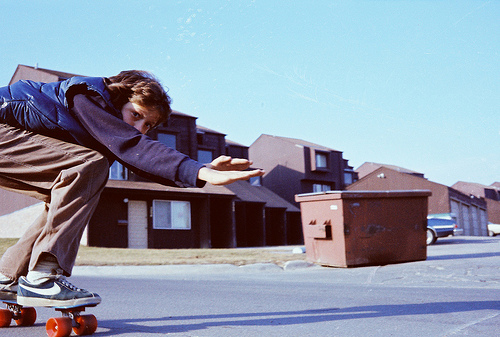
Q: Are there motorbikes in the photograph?
A: No, there are no motorbikes.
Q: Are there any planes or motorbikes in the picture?
A: No, there are no motorbikes or planes.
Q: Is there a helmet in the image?
A: No, there are no helmets.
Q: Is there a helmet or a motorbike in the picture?
A: No, there are no helmets or motorcycles.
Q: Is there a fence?
A: No, there are no fences.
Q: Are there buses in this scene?
A: No, there are no buses.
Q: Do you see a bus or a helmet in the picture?
A: No, there are no buses or helmets.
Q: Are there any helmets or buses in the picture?
A: No, there are no buses or helmets.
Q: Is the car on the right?
A: Yes, the car is on the right of the image.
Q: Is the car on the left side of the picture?
A: No, the car is on the right of the image.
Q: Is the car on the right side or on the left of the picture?
A: The car is on the right of the image.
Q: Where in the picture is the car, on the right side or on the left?
A: The car is on the right of the image.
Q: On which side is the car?
A: The car is on the right of the image.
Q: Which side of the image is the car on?
A: The car is on the right of the image.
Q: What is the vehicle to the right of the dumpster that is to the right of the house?
A: The vehicle is a car.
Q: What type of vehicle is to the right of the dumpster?
A: The vehicle is a car.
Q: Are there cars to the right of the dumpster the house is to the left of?
A: Yes, there is a car to the right of the dumpster.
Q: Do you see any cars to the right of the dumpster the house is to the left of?
A: Yes, there is a car to the right of the dumpster.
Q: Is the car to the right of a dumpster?
A: Yes, the car is to the right of a dumpster.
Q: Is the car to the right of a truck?
A: No, the car is to the right of a dumpster.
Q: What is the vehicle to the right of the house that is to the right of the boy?
A: The vehicle is a car.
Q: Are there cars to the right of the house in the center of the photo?
A: Yes, there is a car to the right of the house.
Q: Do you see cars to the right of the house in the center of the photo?
A: Yes, there is a car to the right of the house.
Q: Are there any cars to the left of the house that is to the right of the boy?
A: No, the car is to the right of the house.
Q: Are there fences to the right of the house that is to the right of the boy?
A: No, there is a car to the right of the house.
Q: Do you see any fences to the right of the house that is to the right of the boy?
A: No, there is a car to the right of the house.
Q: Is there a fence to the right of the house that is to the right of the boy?
A: No, there is a car to the right of the house.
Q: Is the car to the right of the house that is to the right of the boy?
A: Yes, the car is to the right of the house.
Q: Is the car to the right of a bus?
A: No, the car is to the right of the house.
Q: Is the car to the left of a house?
A: No, the car is to the right of a house.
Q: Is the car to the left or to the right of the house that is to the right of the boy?
A: The car is to the right of the house.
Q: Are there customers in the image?
A: No, there are no customers.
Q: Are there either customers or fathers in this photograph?
A: No, there are no customers or fathers.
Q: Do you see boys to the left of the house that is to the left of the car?
A: Yes, there is a boy to the left of the house.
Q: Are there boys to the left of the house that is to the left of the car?
A: Yes, there is a boy to the left of the house.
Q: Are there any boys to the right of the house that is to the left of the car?
A: No, the boy is to the left of the house.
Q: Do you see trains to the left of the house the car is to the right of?
A: No, there is a boy to the left of the house.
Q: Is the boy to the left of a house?
A: Yes, the boy is to the left of a house.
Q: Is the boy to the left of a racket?
A: No, the boy is to the left of a house.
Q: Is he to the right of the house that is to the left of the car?
A: No, the boy is to the left of the house.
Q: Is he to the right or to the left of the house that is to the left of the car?
A: The boy is to the left of the house.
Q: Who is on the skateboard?
A: The boy is on the skateboard.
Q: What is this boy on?
A: The boy is on the skateboard.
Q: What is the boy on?
A: The boy is on the skateboard.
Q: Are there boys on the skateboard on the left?
A: Yes, there is a boy on the skateboard.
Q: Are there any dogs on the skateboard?
A: No, there is a boy on the skateboard.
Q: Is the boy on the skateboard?
A: Yes, the boy is on the skateboard.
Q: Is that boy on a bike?
A: No, the boy is on the skateboard.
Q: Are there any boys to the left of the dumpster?
A: Yes, there is a boy to the left of the dumpster.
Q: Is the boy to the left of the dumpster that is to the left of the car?
A: Yes, the boy is to the left of the dumpster.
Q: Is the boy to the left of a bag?
A: No, the boy is to the left of the dumpster.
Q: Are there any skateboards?
A: Yes, there is a skateboard.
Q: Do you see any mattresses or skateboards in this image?
A: Yes, there is a skateboard.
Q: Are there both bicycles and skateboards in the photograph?
A: No, there is a skateboard but no bikes.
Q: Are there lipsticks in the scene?
A: No, there are no lipsticks.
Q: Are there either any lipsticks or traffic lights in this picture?
A: No, there are no lipsticks or traffic lights.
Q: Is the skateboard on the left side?
A: Yes, the skateboard is on the left of the image.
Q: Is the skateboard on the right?
A: No, the skateboard is on the left of the image.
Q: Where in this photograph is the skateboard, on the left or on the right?
A: The skateboard is on the left of the image.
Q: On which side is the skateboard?
A: The skateboard is on the left of the image.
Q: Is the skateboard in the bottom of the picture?
A: Yes, the skateboard is in the bottom of the image.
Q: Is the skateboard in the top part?
A: No, the skateboard is in the bottom of the image.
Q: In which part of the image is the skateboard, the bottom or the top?
A: The skateboard is in the bottom of the image.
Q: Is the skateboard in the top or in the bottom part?
A: The skateboard is in the bottom of the image.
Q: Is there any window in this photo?
A: Yes, there is a window.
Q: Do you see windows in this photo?
A: Yes, there is a window.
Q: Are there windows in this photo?
A: Yes, there is a window.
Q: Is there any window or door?
A: Yes, there is a window.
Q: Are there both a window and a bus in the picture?
A: No, there is a window but no buses.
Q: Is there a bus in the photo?
A: No, there are no buses.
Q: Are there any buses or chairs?
A: No, there are no buses or chairs.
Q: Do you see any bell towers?
A: No, there are no bell towers.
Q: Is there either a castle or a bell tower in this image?
A: No, there are no bell towers or castles.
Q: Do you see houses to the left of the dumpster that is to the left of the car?
A: Yes, there is a house to the left of the dumpster.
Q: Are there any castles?
A: No, there are no castles.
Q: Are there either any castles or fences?
A: No, there are no castles or fences.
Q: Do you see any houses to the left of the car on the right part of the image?
A: Yes, there is a house to the left of the car.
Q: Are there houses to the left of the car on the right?
A: Yes, there is a house to the left of the car.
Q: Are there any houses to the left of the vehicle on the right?
A: Yes, there is a house to the left of the car.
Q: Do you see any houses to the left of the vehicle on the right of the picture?
A: Yes, there is a house to the left of the car.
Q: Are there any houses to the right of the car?
A: No, the house is to the left of the car.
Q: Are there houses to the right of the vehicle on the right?
A: No, the house is to the left of the car.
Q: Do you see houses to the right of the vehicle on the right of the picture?
A: No, the house is to the left of the car.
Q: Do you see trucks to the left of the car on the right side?
A: No, there is a house to the left of the car.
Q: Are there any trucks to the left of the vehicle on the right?
A: No, there is a house to the left of the car.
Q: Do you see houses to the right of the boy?
A: Yes, there is a house to the right of the boy.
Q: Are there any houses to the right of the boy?
A: Yes, there is a house to the right of the boy.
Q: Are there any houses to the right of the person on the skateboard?
A: Yes, there is a house to the right of the boy.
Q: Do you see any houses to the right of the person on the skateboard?
A: Yes, there is a house to the right of the boy.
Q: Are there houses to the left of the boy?
A: No, the house is to the right of the boy.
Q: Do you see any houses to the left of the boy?
A: No, the house is to the right of the boy.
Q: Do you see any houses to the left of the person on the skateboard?
A: No, the house is to the right of the boy.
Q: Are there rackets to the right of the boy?
A: No, there is a house to the right of the boy.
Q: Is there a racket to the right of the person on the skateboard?
A: No, there is a house to the right of the boy.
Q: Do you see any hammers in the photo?
A: No, there are no hammers.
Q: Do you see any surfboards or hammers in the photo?
A: No, there are no hammers or surfboards.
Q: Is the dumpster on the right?
A: Yes, the dumpster is on the right of the image.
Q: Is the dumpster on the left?
A: No, the dumpster is on the right of the image.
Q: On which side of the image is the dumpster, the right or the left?
A: The dumpster is on the right of the image.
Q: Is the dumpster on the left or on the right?
A: The dumpster is on the right of the image.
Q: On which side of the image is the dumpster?
A: The dumpster is on the right of the image.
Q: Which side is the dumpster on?
A: The dumpster is on the right of the image.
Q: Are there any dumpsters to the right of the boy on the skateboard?
A: Yes, there is a dumpster to the right of the boy.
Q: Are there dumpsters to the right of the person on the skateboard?
A: Yes, there is a dumpster to the right of the boy.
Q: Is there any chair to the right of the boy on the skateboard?
A: No, there is a dumpster to the right of the boy.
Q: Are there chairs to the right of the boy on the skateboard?
A: No, there is a dumpster to the right of the boy.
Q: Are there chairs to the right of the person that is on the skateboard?
A: No, there is a dumpster to the right of the boy.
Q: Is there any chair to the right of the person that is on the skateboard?
A: No, there is a dumpster to the right of the boy.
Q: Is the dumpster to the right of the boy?
A: Yes, the dumpster is to the right of the boy.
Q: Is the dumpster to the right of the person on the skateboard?
A: Yes, the dumpster is to the right of the boy.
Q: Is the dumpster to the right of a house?
A: Yes, the dumpster is to the right of a house.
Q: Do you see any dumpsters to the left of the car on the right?
A: Yes, there is a dumpster to the left of the car.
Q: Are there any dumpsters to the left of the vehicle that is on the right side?
A: Yes, there is a dumpster to the left of the car.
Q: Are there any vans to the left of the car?
A: No, there is a dumpster to the left of the car.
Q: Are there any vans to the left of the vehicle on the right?
A: No, there is a dumpster to the left of the car.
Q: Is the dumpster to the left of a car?
A: Yes, the dumpster is to the left of a car.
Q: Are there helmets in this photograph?
A: No, there are no helmets.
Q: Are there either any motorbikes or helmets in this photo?
A: No, there are no helmets or motorbikes.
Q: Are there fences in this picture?
A: No, there are no fences.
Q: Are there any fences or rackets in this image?
A: No, there are no fences or rackets.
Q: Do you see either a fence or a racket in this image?
A: No, there are no fences or rackets.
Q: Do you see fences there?
A: No, there are no fences.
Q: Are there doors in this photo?
A: Yes, there is a door.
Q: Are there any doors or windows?
A: Yes, there is a door.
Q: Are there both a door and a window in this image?
A: Yes, there are both a door and a window.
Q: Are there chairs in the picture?
A: No, there are no chairs.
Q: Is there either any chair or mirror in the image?
A: No, there are no chairs or mirrors.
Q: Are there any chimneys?
A: No, there are no chimneys.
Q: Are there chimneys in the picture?
A: No, there are no chimneys.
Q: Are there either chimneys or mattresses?
A: No, there are no chimneys or mattresses.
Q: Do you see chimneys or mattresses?
A: No, there are no chimneys or mattresses.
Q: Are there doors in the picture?
A: Yes, there is a door.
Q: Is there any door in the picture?
A: Yes, there is a door.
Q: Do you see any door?
A: Yes, there is a door.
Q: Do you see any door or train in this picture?
A: Yes, there is a door.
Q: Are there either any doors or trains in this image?
A: Yes, there is a door.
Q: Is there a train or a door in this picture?
A: Yes, there is a door.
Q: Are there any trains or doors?
A: Yes, there is a door.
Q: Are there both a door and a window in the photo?
A: Yes, there are both a door and a window.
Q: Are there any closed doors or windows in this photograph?
A: Yes, there is a closed door.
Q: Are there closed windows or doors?
A: Yes, there is a closed door.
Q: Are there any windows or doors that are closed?
A: Yes, the door is closed.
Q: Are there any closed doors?
A: Yes, there is a closed door.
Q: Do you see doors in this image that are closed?
A: Yes, there is a door that is closed.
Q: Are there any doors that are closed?
A: Yes, there is a door that is closed.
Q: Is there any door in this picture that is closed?
A: Yes, there is a door that is closed.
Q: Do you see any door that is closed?
A: Yes, there is a door that is closed.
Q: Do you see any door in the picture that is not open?
A: Yes, there is an closed door.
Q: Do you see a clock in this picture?
A: No, there are no clocks.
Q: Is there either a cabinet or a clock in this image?
A: No, there are no clocks or cabinets.